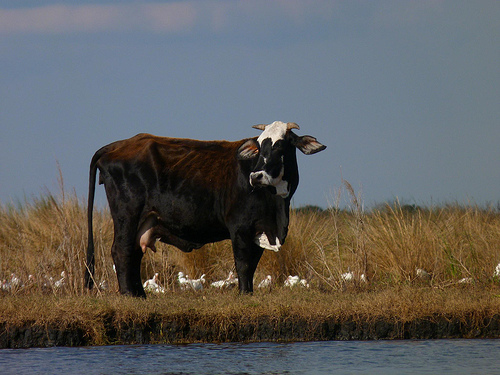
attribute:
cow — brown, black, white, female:
[83, 122, 329, 301]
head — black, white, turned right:
[242, 121, 327, 186]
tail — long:
[83, 145, 99, 294]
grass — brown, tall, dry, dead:
[0, 199, 499, 343]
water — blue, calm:
[6, 343, 498, 374]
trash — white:
[260, 275, 311, 294]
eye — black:
[274, 142, 289, 152]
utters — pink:
[132, 222, 159, 260]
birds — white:
[146, 269, 239, 300]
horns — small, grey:
[248, 117, 301, 132]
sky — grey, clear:
[1, 6, 497, 204]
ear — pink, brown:
[233, 137, 261, 164]